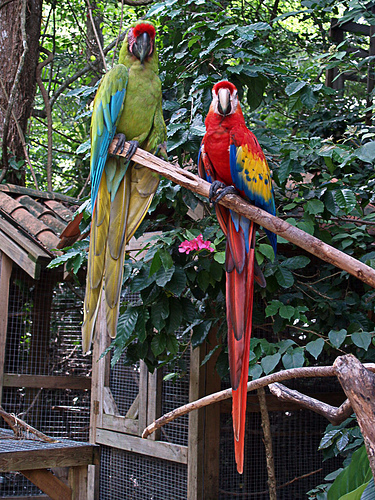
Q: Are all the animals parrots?
A: Yes, all the animals are parrots.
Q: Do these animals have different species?
A: No, all the animals are parrots.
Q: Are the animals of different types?
A: No, all the animals are parrots.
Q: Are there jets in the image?
A: No, there are no jets.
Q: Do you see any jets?
A: No, there are no jets.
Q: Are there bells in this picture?
A: No, there are no bells.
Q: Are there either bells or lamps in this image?
A: No, there are no bells or lamps.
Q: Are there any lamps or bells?
A: No, there are no bells or lamps.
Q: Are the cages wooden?
A: Yes, the cages are wooden.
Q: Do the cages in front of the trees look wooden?
A: Yes, the cages are wooden.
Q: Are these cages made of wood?
A: Yes, the cages are made of wood.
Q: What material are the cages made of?
A: The cages are made of wood.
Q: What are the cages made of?
A: The cages are made of wood.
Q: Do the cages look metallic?
A: No, the cages are wooden.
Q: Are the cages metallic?
A: No, the cages are wooden.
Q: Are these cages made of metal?
A: No, the cages are made of wood.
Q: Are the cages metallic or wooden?
A: The cages are wooden.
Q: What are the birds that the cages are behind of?
A: The birds are parrots.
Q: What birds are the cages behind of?
A: The cages are behind the parrots.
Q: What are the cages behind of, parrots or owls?
A: The cages are behind parrots.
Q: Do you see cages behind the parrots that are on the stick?
A: Yes, there are cages behind the parrots.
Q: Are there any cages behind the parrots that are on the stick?
A: Yes, there are cages behind the parrots.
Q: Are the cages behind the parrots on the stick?
A: Yes, the cages are behind the parrots.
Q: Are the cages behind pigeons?
A: No, the cages are behind the parrots.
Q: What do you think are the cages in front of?
A: The cages are in front of the trees.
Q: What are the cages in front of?
A: The cages are in front of the trees.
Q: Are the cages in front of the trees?
A: Yes, the cages are in front of the trees.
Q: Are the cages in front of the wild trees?
A: Yes, the cages are in front of the trees.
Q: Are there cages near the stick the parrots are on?
A: Yes, there are cages near the stick.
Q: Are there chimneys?
A: No, there are no chimneys.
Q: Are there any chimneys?
A: No, there are no chimneys.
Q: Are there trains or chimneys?
A: No, there are no chimneys or trains.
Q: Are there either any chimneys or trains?
A: No, there are no chimneys or trains.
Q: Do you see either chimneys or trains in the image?
A: No, there are no chimneys or trains.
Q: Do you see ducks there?
A: No, there are no ducks.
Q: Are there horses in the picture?
A: No, there are no horses.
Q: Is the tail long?
A: Yes, the tail is long.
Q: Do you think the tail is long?
A: Yes, the tail is long.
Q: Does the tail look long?
A: Yes, the tail is long.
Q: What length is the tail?
A: The tail is long.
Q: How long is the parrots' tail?
A: The tail is long.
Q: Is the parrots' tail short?
A: No, the tail is long.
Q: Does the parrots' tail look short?
A: No, the tail is long.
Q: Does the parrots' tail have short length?
A: No, the tail is long.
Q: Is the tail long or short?
A: The tail is long.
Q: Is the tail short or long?
A: The tail is long.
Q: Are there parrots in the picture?
A: Yes, there is a parrot.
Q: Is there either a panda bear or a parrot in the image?
A: Yes, there is a parrot.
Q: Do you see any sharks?
A: No, there are no sharks.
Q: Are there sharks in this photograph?
A: No, there are no sharks.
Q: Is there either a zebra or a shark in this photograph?
A: No, there are no sharks or zebras.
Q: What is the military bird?
A: The bird is a parrot.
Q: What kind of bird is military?
A: The bird is a parrot.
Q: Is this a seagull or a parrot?
A: This is a parrot.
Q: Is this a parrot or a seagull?
A: This is a parrot.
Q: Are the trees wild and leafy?
A: Yes, the trees are wild and leafy.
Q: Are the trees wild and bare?
A: No, the trees are wild but leafy.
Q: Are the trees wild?
A: Yes, the trees are wild.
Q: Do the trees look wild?
A: Yes, the trees are wild.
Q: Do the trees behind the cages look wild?
A: Yes, the trees are wild.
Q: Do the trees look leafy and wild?
A: Yes, the trees are leafy and wild.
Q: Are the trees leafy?
A: Yes, the trees are leafy.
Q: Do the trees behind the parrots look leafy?
A: Yes, the trees are leafy.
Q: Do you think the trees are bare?
A: No, the trees are leafy.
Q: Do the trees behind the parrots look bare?
A: No, the trees are leafy.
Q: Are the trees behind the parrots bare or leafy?
A: The trees are leafy.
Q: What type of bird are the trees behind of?
A: The trees are behind the parrots.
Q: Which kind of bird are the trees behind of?
A: The trees are behind the parrots.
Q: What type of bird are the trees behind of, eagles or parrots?
A: The trees are behind parrots.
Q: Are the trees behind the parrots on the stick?
A: Yes, the trees are behind the parrots.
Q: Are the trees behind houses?
A: No, the trees are behind the parrots.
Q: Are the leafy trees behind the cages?
A: Yes, the trees are behind the cages.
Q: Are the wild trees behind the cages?
A: Yes, the trees are behind the cages.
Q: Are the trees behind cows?
A: No, the trees are behind the cages.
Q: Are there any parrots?
A: Yes, there are parrots.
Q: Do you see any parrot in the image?
A: Yes, there are parrots.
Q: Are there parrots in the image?
A: Yes, there are parrots.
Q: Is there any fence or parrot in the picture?
A: Yes, there are parrots.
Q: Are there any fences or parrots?
A: Yes, there are parrots.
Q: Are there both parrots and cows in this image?
A: No, there are parrots but no cows.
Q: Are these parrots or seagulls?
A: These are parrots.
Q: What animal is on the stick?
A: The parrots are on the stick.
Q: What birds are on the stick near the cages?
A: The birds are parrots.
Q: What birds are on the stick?
A: The birds are parrots.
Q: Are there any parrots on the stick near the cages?
A: Yes, there are parrots on the stick.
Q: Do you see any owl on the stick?
A: No, there are parrots on the stick.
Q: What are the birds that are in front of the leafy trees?
A: The birds are parrots.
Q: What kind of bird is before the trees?
A: The birds are parrots.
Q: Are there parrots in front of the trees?
A: Yes, there are parrots in front of the trees.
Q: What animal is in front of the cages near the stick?
A: The parrots are in front of the cages.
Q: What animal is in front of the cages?
A: The parrots are in front of the cages.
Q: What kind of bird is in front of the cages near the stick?
A: The birds are parrots.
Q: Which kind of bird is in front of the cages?
A: The birds are parrots.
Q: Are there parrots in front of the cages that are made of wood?
A: Yes, there are parrots in front of the cages.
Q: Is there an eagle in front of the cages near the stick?
A: No, there are parrots in front of the cages.